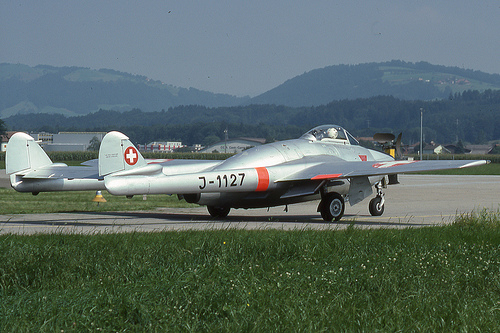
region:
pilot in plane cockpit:
[323, 124, 340, 140]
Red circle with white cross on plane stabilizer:
[122, 145, 139, 163]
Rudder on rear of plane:
[95, 122, 129, 177]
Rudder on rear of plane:
[2, 129, 35, 173]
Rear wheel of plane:
[317, 189, 347, 221]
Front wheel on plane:
[368, 195, 384, 216]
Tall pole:
[419, 105, 424, 162]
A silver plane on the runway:
[1, 120, 492, 220]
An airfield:
[0, 120, 495, 235]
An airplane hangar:
[199, 139, 267, 154]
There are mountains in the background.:
[293, 58, 482, 103]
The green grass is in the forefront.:
[137, 247, 345, 316]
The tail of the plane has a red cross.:
[81, 128, 169, 194]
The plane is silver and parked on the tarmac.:
[87, 122, 498, 218]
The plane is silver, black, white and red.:
[94, 127, 496, 227]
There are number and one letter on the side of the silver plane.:
[171, 167, 271, 192]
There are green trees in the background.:
[168, 106, 316, 120]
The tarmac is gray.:
[426, 181, 472, 215]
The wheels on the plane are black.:
[302, 196, 414, 218]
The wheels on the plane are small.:
[316, 191, 419, 226]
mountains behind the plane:
[3, 12, 498, 223]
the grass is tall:
[1, 207, 498, 332]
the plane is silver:
[4, 115, 494, 225]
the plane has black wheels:
[314, 130, 465, 230]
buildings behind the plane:
[2, 112, 499, 162]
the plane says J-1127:
[184, 160, 271, 211]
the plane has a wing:
[265, 137, 499, 192]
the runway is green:
[1, 181, 496, 231]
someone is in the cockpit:
[290, 113, 374, 155]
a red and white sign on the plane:
[115, 135, 152, 172]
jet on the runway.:
[20, 97, 467, 220]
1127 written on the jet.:
[210, 172, 246, 189]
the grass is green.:
[9, 215, 489, 330]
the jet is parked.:
[19, 103, 479, 215]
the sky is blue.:
[3, 1, 496, 71]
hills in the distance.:
[2, 47, 491, 122]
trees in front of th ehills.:
[3, 82, 494, 145]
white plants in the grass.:
[275, 234, 491, 293]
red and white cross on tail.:
[117, 140, 144, 169]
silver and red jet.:
[16, 85, 473, 217]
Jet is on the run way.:
[35, 104, 457, 227]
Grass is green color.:
[76, 248, 371, 309]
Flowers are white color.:
[181, 226, 470, 315]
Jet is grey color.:
[38, 108, 452, 219]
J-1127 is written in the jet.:
[186, 163, 261, 201]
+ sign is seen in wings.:
[119, 133, 146, 170]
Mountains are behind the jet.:
[6, 41, 497, 164]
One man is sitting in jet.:
[310, 119, 365, 152]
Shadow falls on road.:
[55, 198, 375, 241]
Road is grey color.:
[411, 183, 492, 215]